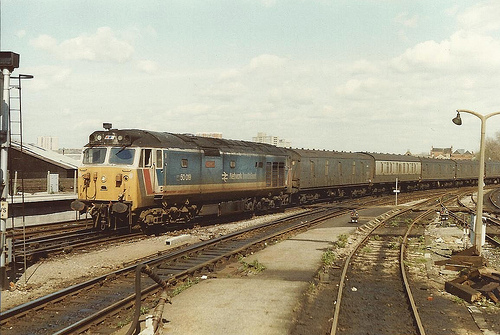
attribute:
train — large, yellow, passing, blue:
[99, 135, 265, 201]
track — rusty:
[18, 201, 73, 236]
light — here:
[452, 111, 474, 128]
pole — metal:
[467, 139, 499, 190]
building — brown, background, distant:
[49, 136, 73, 153]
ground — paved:
[189, 305, 211, 317]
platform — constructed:
[26, 201, 86, 265]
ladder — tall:
[0, 84, 30, 158]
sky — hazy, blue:
[163, 22, 184, 34]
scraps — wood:
[109, 237, 133, 249]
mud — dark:
[72, 244, 99, 257]